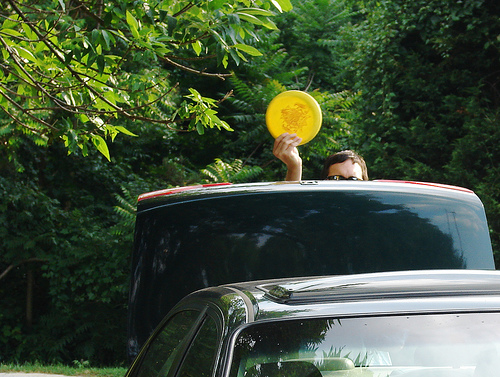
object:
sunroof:
[264, 269, 500, 303]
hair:
[319, 149, 368, 181]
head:
[320, 149, 369, 181]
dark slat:
[269, 271, 500, 305]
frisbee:
[265, 90, 322, 146]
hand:
[272, 132, 302, 169]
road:
[0, 370, 106, 376]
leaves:
[23, 180, 125, 227]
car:
[126, 179, 493, 375]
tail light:
[138, 183, 234, 202]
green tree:
[0, 0, 296, 163]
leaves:
[0, 2, 295, 149]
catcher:
[273, 132, 369, 181]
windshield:
[230, 308, 500, 376]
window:
[171, 316, 223, 376]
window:
[127, 307, 205, 376]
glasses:
[326, 175, 364, 181]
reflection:
[132, 191, 496, 289]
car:
[123, 268, 500, 377]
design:
[280, 102, 311, 133]